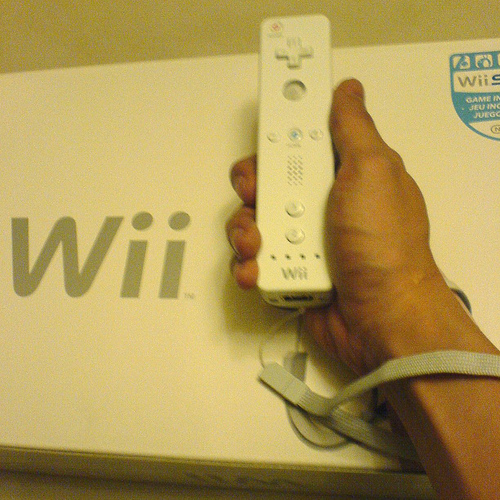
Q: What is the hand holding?
A: A wii remote control.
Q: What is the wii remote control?
A: White.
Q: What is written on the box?
A: Wii.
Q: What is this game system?
A: Wii.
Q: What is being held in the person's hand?
A: Game controller.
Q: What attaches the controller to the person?
A: Strap.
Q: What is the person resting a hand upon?
A: Box.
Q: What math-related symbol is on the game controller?
A: Plus.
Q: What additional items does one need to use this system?
A: Television and console.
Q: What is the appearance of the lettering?
A: Gray.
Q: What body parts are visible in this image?
A: Arm and hand.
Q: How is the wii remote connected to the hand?
A: A strap.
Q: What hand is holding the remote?
A: Right hand.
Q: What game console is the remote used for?
A: Wii.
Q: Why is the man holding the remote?
A: To play Wii.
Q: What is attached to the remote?
A: Gray wristband.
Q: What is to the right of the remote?
A: The person's thumb.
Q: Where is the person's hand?
A: On the box.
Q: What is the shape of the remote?
A: Rectangle.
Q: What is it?
A: Controller.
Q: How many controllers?
A: 1.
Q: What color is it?
A: White.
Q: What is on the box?
A: Letters.